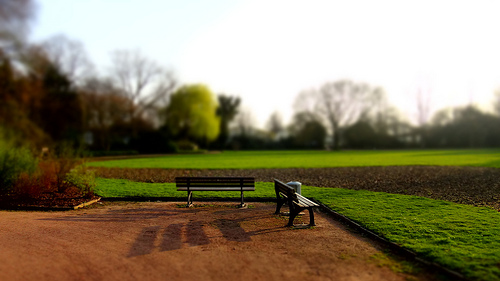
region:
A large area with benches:
[46, 122, 461, 274]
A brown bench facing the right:
[271, 168, 331, 229]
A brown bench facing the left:
[170, 167, 255, 213]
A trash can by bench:
[289, 169, 304, 206]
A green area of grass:
[321, 183, 484, 265]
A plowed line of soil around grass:
[120, 157, 499, 202]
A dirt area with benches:
[22, 173, 329, 270]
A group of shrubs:
[9, 157, 105, 217]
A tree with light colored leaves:
[164, 74, 222, 151]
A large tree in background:
[295, 63, 369, 143]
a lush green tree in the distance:
[166, 83, 219, 141]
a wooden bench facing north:
[173, 175, 253, 207]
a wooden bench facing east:
[270, 175, 317, 226]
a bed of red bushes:
[1, 174, 95, 207]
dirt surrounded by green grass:
[1, 197, 441, 279]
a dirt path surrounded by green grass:
[81, 164, 499, 211]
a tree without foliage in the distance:
[288, 80, 384, 147]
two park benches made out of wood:
[173, 173, 318, 228]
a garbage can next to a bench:
[285, 178, 303, 195]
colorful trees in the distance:
[0, 47, 84, 152]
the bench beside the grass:
[271, 176, 332, 236]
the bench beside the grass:
[170, 168, 259, 215]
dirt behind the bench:
[14, 203, 329, 278]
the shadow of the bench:
[111, 204, 263, 261]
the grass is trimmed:
[86, 151, 489, 278]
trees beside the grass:
[46, 65, 498, 150]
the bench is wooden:
[260, 174, 310, 216]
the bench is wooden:
[170, 176, 252, 198]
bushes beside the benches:
[2, 140, 80, 200]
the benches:
[173, 161, 340, 246]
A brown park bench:
[173, 173, 256, 208]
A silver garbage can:
[285, 178, 302, 197]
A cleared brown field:
[72, 162, 498, 213]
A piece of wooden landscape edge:
[308, 196, 472, 279]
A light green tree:
[162, 83, 219, 143]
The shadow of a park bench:
[121, 210, 316, 260]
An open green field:
[62, 144, 498, 279]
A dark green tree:
[213, 92, 242, 147]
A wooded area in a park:
[0, 0, 498, 210]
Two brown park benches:
[172, 171, 322, 229]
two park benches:
[169, 172, 323, 229]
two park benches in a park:
[172, 171, 319, 226]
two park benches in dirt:
[169, 168, 320, 225]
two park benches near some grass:
[172, 171, 318, 230]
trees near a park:
[3, 26, 498, 147]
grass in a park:
[88, 143, 490, 170]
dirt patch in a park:
[6, 223, 353, 273]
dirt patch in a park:
[302, 165, 495, 195]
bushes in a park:
[2, 143, 97, 210]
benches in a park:
[172, 172, 319, 233]